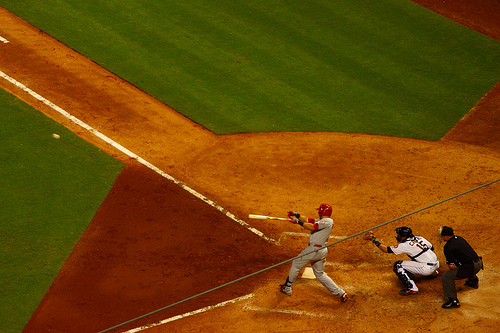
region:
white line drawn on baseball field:
[0, 72, 245, 267]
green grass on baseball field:
[4, 0, 497, 142]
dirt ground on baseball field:
[2, 13, 488, 328]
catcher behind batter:
[350, 216, 440, 303]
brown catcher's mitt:
[356, 228, 377, 249]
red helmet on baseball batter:
[314, 200, 336, 220]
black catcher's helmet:
[389, 223, 417, 248]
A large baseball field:
[12, 13, 489, 319]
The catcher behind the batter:
[370, 213, 435, 281]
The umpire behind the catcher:
[435, 216, 485, 306]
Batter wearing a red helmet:
[308, 196, 338, 221]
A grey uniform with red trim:
[290, 235, 340, 286]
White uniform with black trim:
[397, 230, 437, 298]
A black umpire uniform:
[435, 210, 481, 285]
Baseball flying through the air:
[38, 116, 78, 168]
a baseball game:
[2, 106, 496, 330]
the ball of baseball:
[53, 133, 61, 139]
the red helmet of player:
[317, 203, 332, 217]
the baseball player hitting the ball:
[248, 203, 346, 300]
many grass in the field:
[19, 155, 63, 252]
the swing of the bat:
[249, 210, 334, 277]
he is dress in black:
[440, 226, 482, 307]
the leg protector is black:
[393, 260, 411, 290]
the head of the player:
[316, 203, 331, 218]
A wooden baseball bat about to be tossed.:
[247, 211, 303, 223]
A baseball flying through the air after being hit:
[46, 130, 60, 139]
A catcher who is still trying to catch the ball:
[360, 221, 439, 296]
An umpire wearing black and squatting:
[432, 224, 486, 314]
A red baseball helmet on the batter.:
[315, 201, 332, 219]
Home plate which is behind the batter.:
[298, 264, 319, 279]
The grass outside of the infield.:
[0, 0, 497, 141]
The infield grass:
[0, 86, 127, 330]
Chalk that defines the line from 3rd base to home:
[112, 288, 334, 331]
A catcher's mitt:
[361, 230, 377, 240]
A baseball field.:
[4, 3, 497, 325]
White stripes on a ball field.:
[2, 70, 292, 331]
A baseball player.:
[250, 200, 353, 308]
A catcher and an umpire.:
[360, 219, 488, 311]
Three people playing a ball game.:
[244, 203, 486, 315]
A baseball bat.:
[246, 210, 298, 222]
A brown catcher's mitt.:
[360, 227, 377, 241]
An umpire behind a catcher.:
[366, 222, 486, 314]